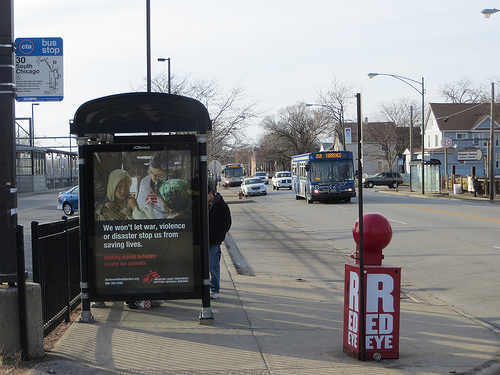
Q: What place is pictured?
A: It is a road.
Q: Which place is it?
A: It is a road.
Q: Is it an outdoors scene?
A: Yes, it is outdoors.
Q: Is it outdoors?
A: Yes, it is outdoors.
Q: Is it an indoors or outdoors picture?
A: It is outdoors.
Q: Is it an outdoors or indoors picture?
A: It is outdoors.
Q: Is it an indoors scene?
A: No, it is outdoors.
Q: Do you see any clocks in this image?
A: No, there are no clocks.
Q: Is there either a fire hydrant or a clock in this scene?
A: No, there are no clocks or fire hydrants.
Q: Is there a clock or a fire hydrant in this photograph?
A: No, there are no clocks or fire hydrants.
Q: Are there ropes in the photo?
A: No, there are no ropes.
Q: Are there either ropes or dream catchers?
A: No, there are no ropes or dream catchers.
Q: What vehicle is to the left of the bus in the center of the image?
A: The vehicle is a car.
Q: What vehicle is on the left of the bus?
A: The vehicle is a car.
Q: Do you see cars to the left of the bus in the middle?
A: Yes, there is a car to the left of the bus.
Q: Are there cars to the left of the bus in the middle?
A: Yes, there is a car to the left of the bus.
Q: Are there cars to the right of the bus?
A: No, the car is to the left of the bus.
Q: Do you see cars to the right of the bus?
A: No, the car is to the left of the bus.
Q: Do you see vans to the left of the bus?
A: No, there is a car to the left of the bus.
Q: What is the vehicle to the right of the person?
A: The vehicle is a car.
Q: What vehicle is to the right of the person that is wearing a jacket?
A: The vehicle is a car.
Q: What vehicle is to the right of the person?
A: The vehicle is a car.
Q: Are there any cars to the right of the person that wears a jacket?
A: Yes, there is a car to the right of the person.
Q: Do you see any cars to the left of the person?
A: No, the car is to the right of the person.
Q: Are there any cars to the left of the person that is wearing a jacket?
A: No, the car is to the right of the person.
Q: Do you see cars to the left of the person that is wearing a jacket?
A: No, the car is to the right of the person.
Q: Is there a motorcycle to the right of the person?
A: No, there is a car to the right of the person.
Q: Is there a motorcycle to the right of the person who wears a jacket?
A: No, there is a car to the right of the person.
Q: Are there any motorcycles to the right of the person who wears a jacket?
A: No, there is a car to the right of the person.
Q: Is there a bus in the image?
A: Yes, there is a bus.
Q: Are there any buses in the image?
A: Yes, there is a bus.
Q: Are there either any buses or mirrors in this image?
A: Yes, there is a bus.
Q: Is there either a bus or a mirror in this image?
A: Yes, there is a bus.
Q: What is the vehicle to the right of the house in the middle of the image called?
A: The vehicle is a bus.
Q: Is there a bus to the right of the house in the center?
A: Yes, there is a bus to the right of the house.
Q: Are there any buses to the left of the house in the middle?
A: No, the bus is to the right of the house.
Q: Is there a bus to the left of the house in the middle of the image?
A: No, the bus is to the right of the house.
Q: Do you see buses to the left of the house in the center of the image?
A: No, the bus is to the right of the house.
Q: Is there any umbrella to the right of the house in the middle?
A: No, there is a bus to the right of the house.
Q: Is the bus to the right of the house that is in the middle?
A: Yes, the bus is to the right of the house.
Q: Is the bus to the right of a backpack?
A: No, the bus is to the right of the house.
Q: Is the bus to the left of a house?
A: No, the bus is to the right of a house.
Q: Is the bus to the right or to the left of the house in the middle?
A: The bus is to the right of the house.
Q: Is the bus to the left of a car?
A: No, the bus is to the right of a car.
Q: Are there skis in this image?
A: No, there are no skis.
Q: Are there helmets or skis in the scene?
A: No, there are no skis or helmets.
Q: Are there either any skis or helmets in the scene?
A: No, there are no skis or helmets.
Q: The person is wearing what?
A: The person is wearing a jacket.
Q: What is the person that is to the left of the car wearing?
A: The person is wearing a jacket.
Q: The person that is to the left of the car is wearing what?
A: The person is wearing a jacket.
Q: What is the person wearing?
A: The person is wearing a jacket.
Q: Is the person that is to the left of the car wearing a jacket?
A: Yes, the person is wearing a jacket.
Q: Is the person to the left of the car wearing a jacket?
A: Yes, the person is wearing a jacket.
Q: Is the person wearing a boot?
A: No, the person is wearing a jacket.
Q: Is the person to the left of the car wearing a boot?
A: No, the person is wearing a jacket.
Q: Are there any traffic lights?
A: No, there are no traffic lights.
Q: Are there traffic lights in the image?
A: No, there are no traffic lights.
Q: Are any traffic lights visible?
A: No, there are no traffic lights.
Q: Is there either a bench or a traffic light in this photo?
A: No, there are no traffic lights or benches.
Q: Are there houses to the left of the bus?
A: Yes, there is a house to the left of the bus.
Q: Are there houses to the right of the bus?
A: No, the house is to the left of the bus.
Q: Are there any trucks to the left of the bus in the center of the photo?
A: No, there is a house to the left of the bus.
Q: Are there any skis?
A: No, there are no skis.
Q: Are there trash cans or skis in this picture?
A: No, there are no skis or trash cans.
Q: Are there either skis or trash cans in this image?
A: No, there are no skis or trash cans.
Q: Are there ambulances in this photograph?
A: No, there are no ambulances.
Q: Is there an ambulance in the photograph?
A: No, there are no ambulances.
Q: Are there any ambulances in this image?
A: No, there are no ambulances.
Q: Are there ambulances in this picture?
A: No, there are no ambulances.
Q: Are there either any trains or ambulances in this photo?
A: No, there are no ambulances or trains.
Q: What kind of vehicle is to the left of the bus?
A: The vehicle is a car.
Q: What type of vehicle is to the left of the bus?
A: The vehicle is a car.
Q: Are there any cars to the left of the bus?
A: Yes, there is a car to the left of the bus.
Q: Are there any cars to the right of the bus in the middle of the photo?
A: No, the car is to the left of the bus.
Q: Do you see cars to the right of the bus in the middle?
A: No, the car is to the left of the bus.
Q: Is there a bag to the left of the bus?
A: No, there is a car to the left of the bus.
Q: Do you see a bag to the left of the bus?
A: No, there is a car to the left of the bus.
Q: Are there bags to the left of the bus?
A: No, there is a car to the left of the bus.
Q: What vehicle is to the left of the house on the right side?
A: The vehicle is a car.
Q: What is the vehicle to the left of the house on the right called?
A: The vehicle is a car.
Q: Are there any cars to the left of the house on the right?
A: Yes, there is a car to the left of the house.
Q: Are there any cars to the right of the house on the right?
A: No, the car is to the left of the house.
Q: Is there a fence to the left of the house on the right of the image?
A: No, there is a car to the left of the house.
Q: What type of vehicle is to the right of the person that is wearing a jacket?
A: The vehicle is a car.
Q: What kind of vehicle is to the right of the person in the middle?
A: The vehicle is a car.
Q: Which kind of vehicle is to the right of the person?
A: The vehicle is a car.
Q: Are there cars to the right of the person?
A: Yes, there is a car to the right of the person.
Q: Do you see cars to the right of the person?
A: Yes, there is a car to the right of the person.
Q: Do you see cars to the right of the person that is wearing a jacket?
A: Yes, there is a car to the right of the person.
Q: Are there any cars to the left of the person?
A: No, the car is to the right of the person.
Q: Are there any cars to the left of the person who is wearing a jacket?
A: No, the car is to the right of the person.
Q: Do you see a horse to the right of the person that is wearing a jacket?
A: No, there is a car to the right of the person.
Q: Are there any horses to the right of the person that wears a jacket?
A: No, there is a car to the right of the person.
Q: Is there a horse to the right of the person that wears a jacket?
A: No, there is a car to the right of the person.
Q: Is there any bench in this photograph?
A: No, there are no benches.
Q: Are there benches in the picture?
A: No, there are no benches.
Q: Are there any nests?
A: No, there are no nests.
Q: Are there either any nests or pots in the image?
A: No, there are no nests or pots.